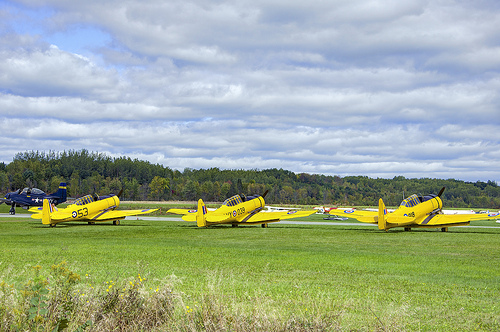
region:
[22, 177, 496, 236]
three yellow planes parked in a row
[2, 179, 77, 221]
a dark blue plane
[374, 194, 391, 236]
yellow tail on a plane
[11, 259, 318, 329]
natural plants on side of grassy field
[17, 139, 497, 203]
dense forest in the landscape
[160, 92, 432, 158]
clouds in a sky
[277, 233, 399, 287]
part of a grassy field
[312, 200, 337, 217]
red sticker on the wing of a plane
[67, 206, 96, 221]
053 on side of plane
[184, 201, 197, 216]
bullseye symbol on wing of plane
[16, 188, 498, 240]
three yellow airplanes on the ground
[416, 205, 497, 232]
right wing of an airplane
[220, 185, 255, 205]
cockpit of an airplane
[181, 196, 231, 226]
tail of an airplane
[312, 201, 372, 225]
left wing of an airplane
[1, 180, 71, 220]
blue airplane on the ground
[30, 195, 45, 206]
star on the side of the airplane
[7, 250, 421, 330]
weeds in front of the field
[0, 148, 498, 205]
row of trees beyond the field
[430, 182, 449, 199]
propeller blade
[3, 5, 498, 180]
Sky full of clouds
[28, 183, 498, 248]
Three yellow single prop airplanes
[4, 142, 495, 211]
Trees under the sky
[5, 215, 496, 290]
green lawn where the planes are parked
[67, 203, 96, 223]
The number 53 on the first yellow plane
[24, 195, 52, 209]
Star on the dark blue airplane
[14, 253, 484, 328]
Wildflowers and tall grass in the foreground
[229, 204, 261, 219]
The number on the middle airplane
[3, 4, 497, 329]
Airplanes in a beautiful country scene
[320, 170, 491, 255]
this is a plane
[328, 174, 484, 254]
the plane is yellow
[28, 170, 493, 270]
three yellow planes together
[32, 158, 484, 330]
planes are sitting in a field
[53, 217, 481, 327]
the field is green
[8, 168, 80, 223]
this is a blue plane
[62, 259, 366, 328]
brown weeds next to field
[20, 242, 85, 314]
yellow flowers next to field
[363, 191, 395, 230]
tail of the plane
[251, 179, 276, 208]
propeller of the plain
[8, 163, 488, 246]
Four planes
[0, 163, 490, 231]
The planes are all grounded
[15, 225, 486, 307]
A field made of grass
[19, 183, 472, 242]
The yellow planes are parked on the grass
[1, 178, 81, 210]
The blue plane is parked on pavement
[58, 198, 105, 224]
Number 53 on the side of the plane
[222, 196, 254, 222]
Number 239 on the side of the plane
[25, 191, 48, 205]
A star on the side of the blue plane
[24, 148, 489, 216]
A forest full of trees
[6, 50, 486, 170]
The sky is full of white clouds